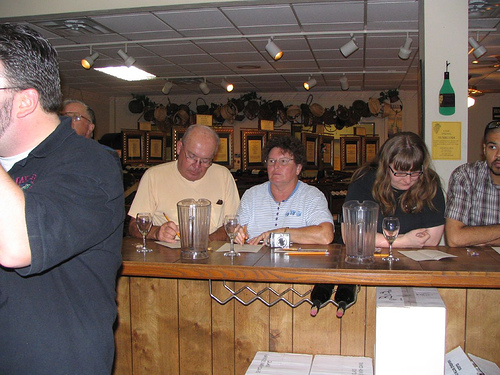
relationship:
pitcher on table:
[175, 196, 213, 260] [120, 240, 484, 344]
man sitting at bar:
[126, 122, 240, 242] [114, 230, 498, 373]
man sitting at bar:
[126, 122, 240, 242] [67, 101, 499, 333]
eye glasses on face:
[176, 149, 214, 167] [170, 115, 224, 175]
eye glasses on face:
[265, 154, 295, 169] [265, 145, 295, 186]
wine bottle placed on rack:
[307, 284, 334, 316] [208, 279, 317, 318]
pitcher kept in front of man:
[175, 196, 213, 260] [147, 124, 235, 199]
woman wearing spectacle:
[230, 134, 334, 244] [264, 152, 291, 167]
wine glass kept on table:
[134, 212, 156, 253] [204, 256, 305, 281]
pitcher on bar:
[175, 196, 213, 260] [114, 230, 498, 373]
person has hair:
[338, 131, 448, 247] [352, 130, 440, 215]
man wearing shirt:
[126, 122, 240, 242] [129, 159, 240, 251]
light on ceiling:
[263, 37, 283, 60] [0, 0, 499, 97]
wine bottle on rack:
[331, 284, 355, 320] [207, 280, 361, 308]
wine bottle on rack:
[307, 284, 335, 314] [207, 280, 361, 308]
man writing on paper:
[126, 122, 240, 242] [157, 236, 192, 248]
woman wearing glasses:
[230, 134, 334, 244] [262, 157, 295, 164]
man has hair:
[126, 122, 240, 242] [0, 22, 60, 110]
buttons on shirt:
[270, 203, 280, 225] [233, 181, 334, 239]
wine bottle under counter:
[307, 284, 334, 316] [111, 236, 496, 371]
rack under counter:
[206, 282, 360, 309] [111, 236, 496, 371]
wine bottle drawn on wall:
[437, 70, 455, 115] [417, 0, 469, 205]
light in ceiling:
[263, 37, 283, 60] [0, 0, 499, 97]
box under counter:
[373, 286, 447, 372] [111, 236, 496, 371]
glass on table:
[220, 216, 241, 250] [110, 237, 499, 373]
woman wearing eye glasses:
[230, 134, 334, 244] [265, 154, 295, 169]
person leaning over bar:
[338, 131, 448, 247] [114, 230, 498, 373]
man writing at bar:
[129, 122, 240, 241] [114, 230, 498, 373]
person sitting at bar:
[338, 131, 448, 247] [114, 230, 498, 373]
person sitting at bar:
[338, 134, 442, 247] [114, 230, 498, 373]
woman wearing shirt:
[227, 134, 334, 262] [238, 183, 333, 230]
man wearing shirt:
[126, 122, 240, 242] [129, 161, 239, 240]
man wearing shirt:
[126, 122, 240, 242] [5, 117, 125, 361]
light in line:
[77, 49, 96, 68] [75, 45, 365, 58]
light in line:
[115, 46, 131, 60] [75, 45, 365, 58]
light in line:
[263, 37, 283, 60] [75, 45, 365, 58]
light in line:
[338, 37, 351, 48] [75, 45, 365, 58]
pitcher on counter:
[175, 196, 213, 260] [130, 230, 486, 290]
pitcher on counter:
[175, 196, 220, 259] [129, 242, 479, 287]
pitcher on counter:
[175, 196, 213, 260] [150, 242, 484, 278]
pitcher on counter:
[175, 196, 213, 260] [135, 233, 478, 283]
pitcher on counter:
[175, 196, 213, 260] [129, 242, 479, 282]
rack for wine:
[206, 283, 367, 318] [305, 279, 357, 323]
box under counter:
[373, 286, 449, 370] [135, 237, 476, 280]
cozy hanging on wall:
[435, 70, 459, 114] [419, 0, 464, 198]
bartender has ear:
[0, 20, 127, 371] [9, 80, 49, 120]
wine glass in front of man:
[134, 210, 158, 253] [118, 111, 240, 239]